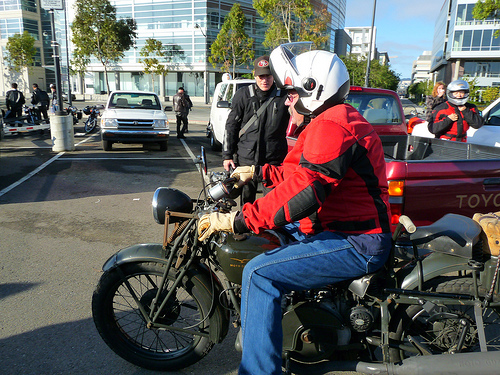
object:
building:
[0, 0, 347, 103]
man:
[222, 59, 286, 170]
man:
[230, 50, 386, 317]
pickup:
[349, 89, 500, 226]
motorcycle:
[90, 146, 500, 363]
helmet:
[270, 40, 351, 117]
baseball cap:
[254, 56, 272, 76]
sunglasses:
[286, 94, 299, 101]